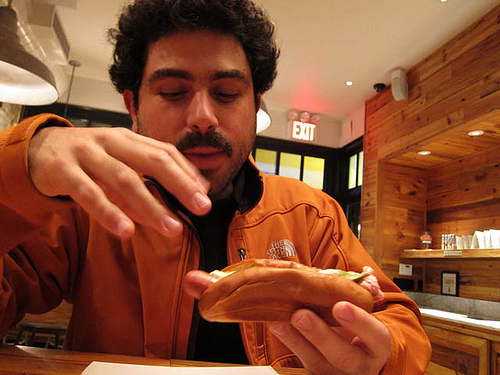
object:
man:
[0, 0, 434, 374]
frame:
[438, 269, 458, 297]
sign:
[291, 119, 316, 141]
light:
[249, 96, 272, 135]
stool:
[1, 299, 74, 349]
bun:
[196, 257, 373, 328]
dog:
[178, 258, 386, 324]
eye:
[209, 86, 241, 103]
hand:
[27, 126, 212, 240]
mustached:
[169, 129, 234, 158]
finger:
[60, 142, 135, 241]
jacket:
[0, 114, 433, 374]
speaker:
[388, 68, 410, 101]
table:
[0, 343, 318, 374]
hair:
[105, 0, 282, 115]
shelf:
[401, 247, 499, 260]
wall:
[58, 75, 341, 149]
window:
[252, 134, 336, 198]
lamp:
[0, 0, 58, 107]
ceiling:
[38, 0, 499, 120]